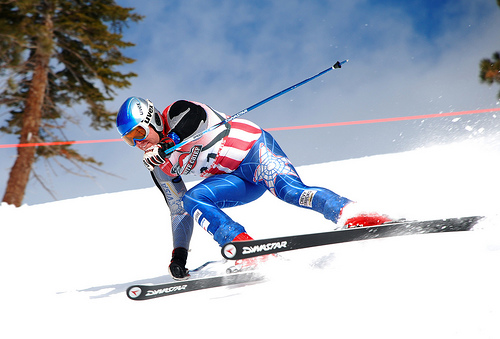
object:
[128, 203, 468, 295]
skis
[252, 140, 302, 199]
star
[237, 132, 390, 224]
leg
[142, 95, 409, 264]
ski suit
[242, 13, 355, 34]
sky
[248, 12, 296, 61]
clouds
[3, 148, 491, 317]
snow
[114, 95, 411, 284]
person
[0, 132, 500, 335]
ice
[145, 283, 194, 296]
letters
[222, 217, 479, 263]
black ski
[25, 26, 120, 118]
tree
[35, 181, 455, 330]
mountain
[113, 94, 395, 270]
person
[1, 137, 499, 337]
snow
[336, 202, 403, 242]
shoe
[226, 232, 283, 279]
shoe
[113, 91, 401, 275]
suit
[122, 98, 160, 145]
goggles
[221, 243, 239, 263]
design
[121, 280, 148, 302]
design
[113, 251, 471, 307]
ski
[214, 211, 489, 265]
ski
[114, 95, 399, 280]
skier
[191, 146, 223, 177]
race bib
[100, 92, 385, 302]
person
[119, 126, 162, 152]
goggles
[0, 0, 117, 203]
trunk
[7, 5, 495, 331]
picture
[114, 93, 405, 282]
man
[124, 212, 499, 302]
skis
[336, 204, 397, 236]
foot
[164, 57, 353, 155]
stroke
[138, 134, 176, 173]
hand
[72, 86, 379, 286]
person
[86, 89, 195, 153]
helmet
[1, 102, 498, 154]
red light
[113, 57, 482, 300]
skier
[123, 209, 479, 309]
black skis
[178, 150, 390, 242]
pants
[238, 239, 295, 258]
print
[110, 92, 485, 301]
person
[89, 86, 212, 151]
helmet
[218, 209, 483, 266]
skiing board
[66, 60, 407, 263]
man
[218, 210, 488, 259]
ski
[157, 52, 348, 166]
ski pole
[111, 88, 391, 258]
man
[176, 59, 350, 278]
ski poles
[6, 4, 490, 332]
photo